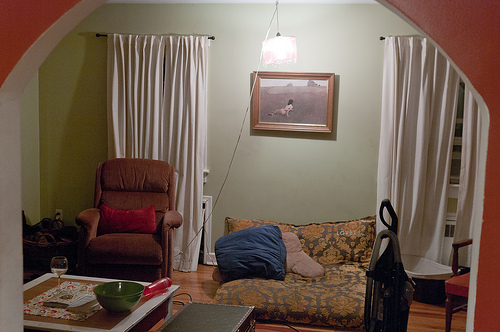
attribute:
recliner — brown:
[69, 148, 180, 270]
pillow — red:
[98, 203, 158, 237]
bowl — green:
[93, 281, 144, 314]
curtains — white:
[96, 22, 211, 270]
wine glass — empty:
[45, 252, 69, 291]